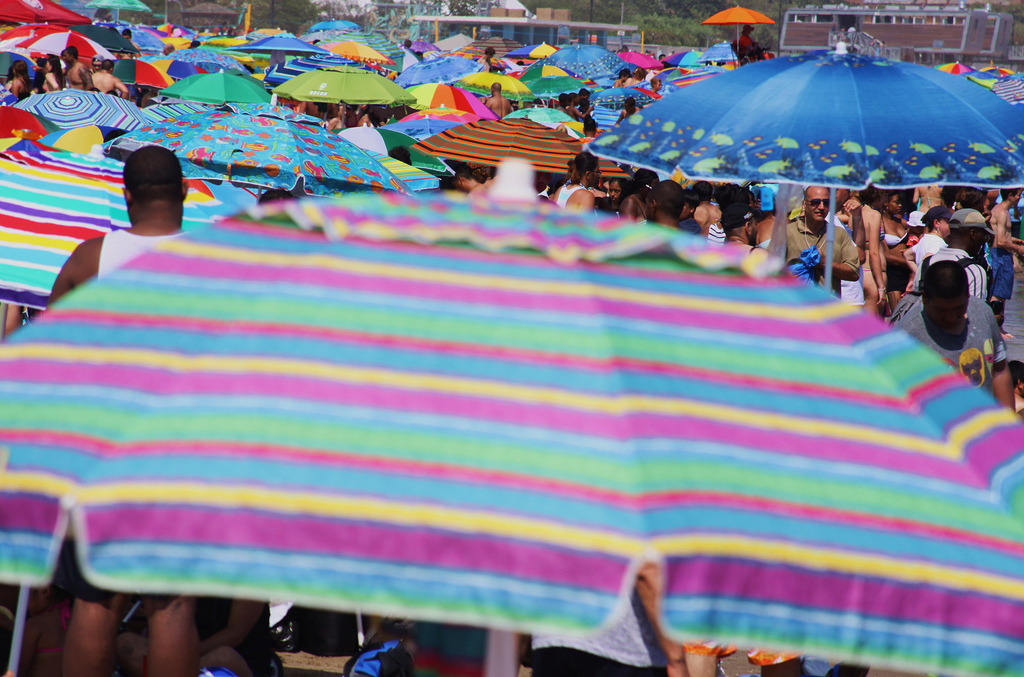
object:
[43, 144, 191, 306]
man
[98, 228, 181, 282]
shirt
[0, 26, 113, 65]
umbrella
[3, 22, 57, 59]
umbrella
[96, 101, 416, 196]
umbrella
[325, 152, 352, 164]
fish pattern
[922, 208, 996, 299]
man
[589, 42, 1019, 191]
blue umbrella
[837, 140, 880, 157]
green fish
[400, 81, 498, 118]
umbrella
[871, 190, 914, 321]
woman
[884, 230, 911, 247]
white bikini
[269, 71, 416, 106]
green umbrella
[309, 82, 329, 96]
white logo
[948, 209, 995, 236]
ball cap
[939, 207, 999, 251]
man's head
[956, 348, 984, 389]
luchadore face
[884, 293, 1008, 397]
man's t-shirt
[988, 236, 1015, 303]
board shorts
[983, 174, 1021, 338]
young man